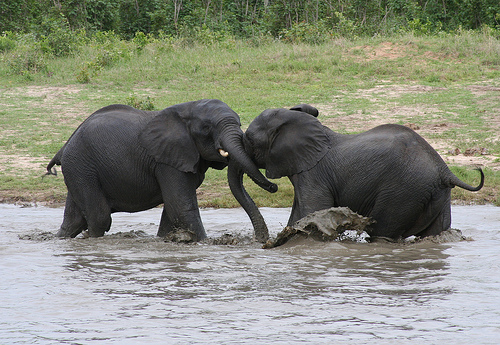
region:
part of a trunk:
[252, 172, 279, 187]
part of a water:
[324, 295, 352, 325]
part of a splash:
[323, 205, 365, 240]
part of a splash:
[316, 223, 346, 268]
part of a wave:
[356, 275, 393, 314]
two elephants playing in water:
[42, 66, 487, 254]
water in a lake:
[6, 240, 496, 342]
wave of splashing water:
[277, 203, 372, 245]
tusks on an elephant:
[214, 143, 231, 160]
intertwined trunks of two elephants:
[215, 124, 280, 250]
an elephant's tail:
[447, 159, 490, 194]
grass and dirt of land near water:
[329, 48, 480, 118]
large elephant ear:
[135, 106, 209, 178]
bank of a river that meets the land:
[2, 190, 60, 211]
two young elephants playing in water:
[35, 81, 481, 256]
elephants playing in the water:
[42, 82, 482, 295]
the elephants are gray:
[27, 83, 489, 245]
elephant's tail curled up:
[440, 157, 497, 212]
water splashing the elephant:
[249, 198, 375, 263]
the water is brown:
[5, 196, 497, 338]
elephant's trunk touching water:
[221, 161, 273, 247]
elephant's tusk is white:
[205, 140, 233, 160]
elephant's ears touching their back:
[130, 110, 353, 179]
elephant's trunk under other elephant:
[225, 145, 293, 209]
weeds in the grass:
[1, 23, 175, 98]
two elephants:
[45, 96, 487, 241]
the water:
[138, 273, 311, 341]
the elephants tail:
[462, 152, 491, 194]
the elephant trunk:
[227, 137, 279, 194]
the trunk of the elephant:
[232, 189, 282, 251]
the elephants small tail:
[32, 154, 57, 185]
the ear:
[139, 121, 199, 168]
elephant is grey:
[58, 102, 248, 242]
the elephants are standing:
[39, 91, 486, 251]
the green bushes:
[186, 9, 278, 31]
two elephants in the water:
[16, 43, 480, 280]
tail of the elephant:
[453, 157, 488, 205]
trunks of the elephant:
[220, 140, 275, 249]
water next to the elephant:
[149, 256, 279, 333]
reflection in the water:
[336, 250, 454, 330]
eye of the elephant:
[188, 115, 223, 142]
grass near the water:
[215, 57, 292, 96]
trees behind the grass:
[160, 3, 327, 44]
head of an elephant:
[241, 95, 321, 160]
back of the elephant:
[357, 99, 439, 156]